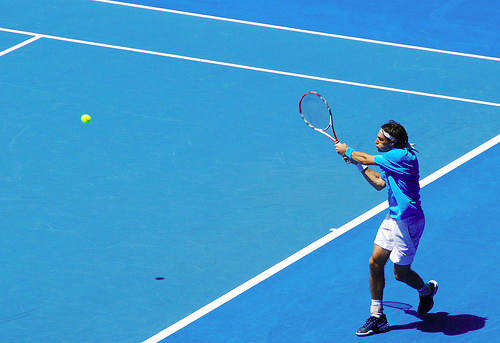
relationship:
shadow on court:
[153, 274, 167, 284] [1, 0, 499, 343]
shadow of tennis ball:
[153, 274, 167, 284] [78, 111, 92, 127]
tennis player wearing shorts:
[332, 119, 440, 338] [372, 209, 426, 267]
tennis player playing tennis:
[332, 119, 440, 338] [76, 82, 350, 167]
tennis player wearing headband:
[332, 119, 440, 338] [377, 127, 401, 145]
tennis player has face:
[332, 119, 440, 338] [374, 131, 385, 153]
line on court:
[106, 1, 498, 61] [1, 0, 499, 343]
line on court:
[1, 25, 499, 109] [1, 0, 499, 343]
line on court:
[127, 127, 499, 341] [1, 0, 499, 343]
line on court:
[1, 32, 42, 71] [1, 0, 499, 343]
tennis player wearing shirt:
[332, 119, 440, 338] [374, 146, 424, 222]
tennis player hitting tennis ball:
[332, 119, 440, 338] [78, 111, 92, 127]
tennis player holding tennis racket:
[332, 119, 440, 338] [296, 88, 351, 164]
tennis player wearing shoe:
[332, 119, 440, 338] [351, 311, 389, 338]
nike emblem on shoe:
[375, 317, 387, 329] [351, 311, 389, 338]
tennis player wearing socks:
[332, 119, 440, 338] [367, 283, 429, 319]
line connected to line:
[1, 32, 42, 71] [1, 25, 499, 109]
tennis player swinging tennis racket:
[332, 119, 440, 338] [296, 88, 351, 164]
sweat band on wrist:
[342, 145, 356, 161] [343, 144, 354, 163]